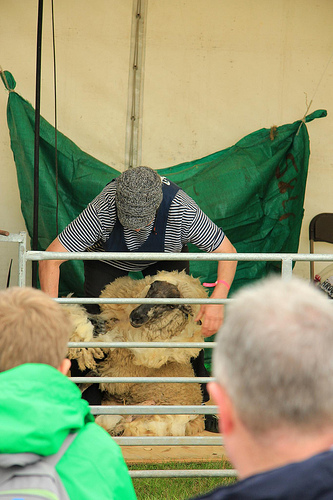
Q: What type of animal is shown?
A: Sheep.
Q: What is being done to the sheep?
A: Shearing.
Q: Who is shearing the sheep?
A: Man standing behind the sheep.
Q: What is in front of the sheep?
A: Fence.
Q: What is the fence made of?
A: Metal.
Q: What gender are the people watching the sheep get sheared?
A: Male.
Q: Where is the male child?
A: Left side of the image.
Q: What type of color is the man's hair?
A: Gray.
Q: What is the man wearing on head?
A: Hat.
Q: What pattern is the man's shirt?
A: Striped.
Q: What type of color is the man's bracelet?
A: Pink.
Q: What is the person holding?
A: Sheep.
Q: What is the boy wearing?
A: Backpack.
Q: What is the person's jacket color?
A: Green.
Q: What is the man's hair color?
A: Gray.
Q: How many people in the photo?
A: Three.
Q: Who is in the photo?
A: Men.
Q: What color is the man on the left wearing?
A: Green.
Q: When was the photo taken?
A: Day time.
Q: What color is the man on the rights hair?
A: Gray.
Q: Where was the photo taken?
A: On a sheep farm.